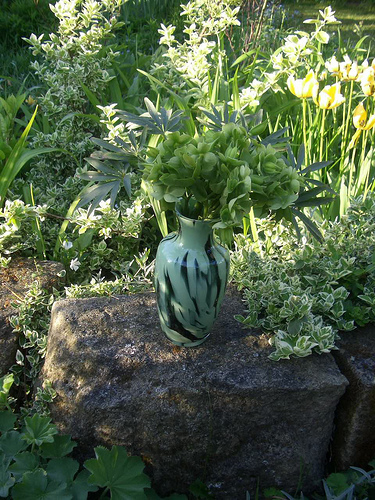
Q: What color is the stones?
A: Grey.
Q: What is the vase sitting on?
A: A rock.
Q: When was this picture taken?
A: During the day.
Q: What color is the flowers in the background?
A: Yellow.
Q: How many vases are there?
A: 1.